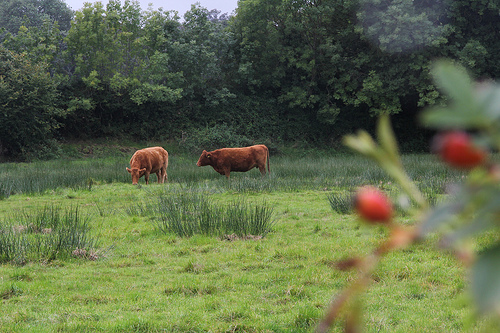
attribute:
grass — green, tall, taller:
[74, 132, 121, 252]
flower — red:
[317, 166, 412, 227]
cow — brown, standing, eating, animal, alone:
[193, 135, 272, 179]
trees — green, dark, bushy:
[69, 9, 282, 145]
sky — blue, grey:
[63, 0, 309, 46]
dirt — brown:
[36, 219, 230, 315]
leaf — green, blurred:
[422, 56, 484, 130]